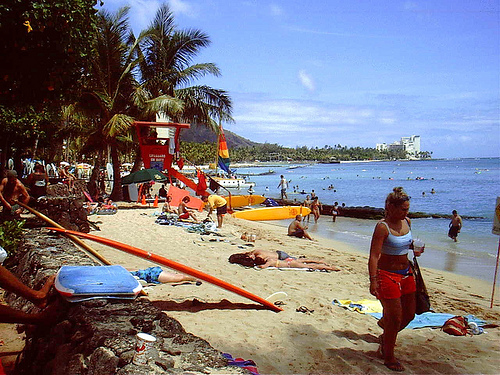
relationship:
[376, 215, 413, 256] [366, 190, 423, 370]
tank top of woman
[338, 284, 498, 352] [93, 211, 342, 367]
towel on sand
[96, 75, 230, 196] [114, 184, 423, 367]
lifeguard on beach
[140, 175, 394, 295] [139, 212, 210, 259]
subathers on sand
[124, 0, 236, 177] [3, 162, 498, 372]
palm tree on beach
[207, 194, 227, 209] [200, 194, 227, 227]
shirt on person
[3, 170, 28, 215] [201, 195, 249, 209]
man without shirt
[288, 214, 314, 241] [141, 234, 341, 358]
man on beach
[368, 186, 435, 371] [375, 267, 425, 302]
woman wearing shorts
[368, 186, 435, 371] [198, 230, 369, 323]
woman on beach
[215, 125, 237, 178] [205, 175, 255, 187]
flag on boat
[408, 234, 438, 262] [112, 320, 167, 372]
cup on ledge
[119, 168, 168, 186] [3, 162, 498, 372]
umbrella on beach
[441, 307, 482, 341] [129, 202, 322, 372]
bag on sand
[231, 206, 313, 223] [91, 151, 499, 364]
boards by beach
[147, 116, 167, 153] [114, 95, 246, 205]
guard red booth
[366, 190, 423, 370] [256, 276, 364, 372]
woman walking on beach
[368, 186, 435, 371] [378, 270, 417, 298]
woman in shorts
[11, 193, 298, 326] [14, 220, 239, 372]
skis leaning against wall